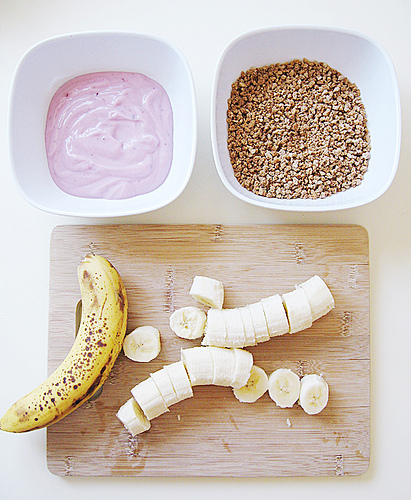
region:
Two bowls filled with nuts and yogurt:
[12, 31, 408, 222]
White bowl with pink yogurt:
[14, 21, 198, 222]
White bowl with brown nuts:
[216, 37, 392, 207]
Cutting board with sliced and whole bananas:
[12, 223, 394, 486]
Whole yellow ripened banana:
[0, 251, 126, 437]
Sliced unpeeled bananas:
[140, 280, 339, 417]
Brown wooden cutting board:
[43, 223, 374, 475]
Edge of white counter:
[323, 480, 408, 497]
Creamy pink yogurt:
[49, 83, 164, 190]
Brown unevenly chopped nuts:
[232, 64, 369, 199]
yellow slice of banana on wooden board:
[294, 274, 339, 332]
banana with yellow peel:
[45, 268, 114, 413]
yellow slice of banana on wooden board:
[290, 373, 339, 427]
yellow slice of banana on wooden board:
[145, 368, 195, 422]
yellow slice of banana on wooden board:
[99, 402, 160, 440]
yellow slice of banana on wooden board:
[182, 265, 231, 313]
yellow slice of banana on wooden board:
[204, 349, 247, 393]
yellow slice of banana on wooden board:
[125, 324, 167, 370]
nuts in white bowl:
[259, 64, 375, 173]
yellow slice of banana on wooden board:
[226, 293, 280, 336]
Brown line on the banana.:
[66, 359, 114, 407]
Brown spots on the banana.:
[62, 343, 105, 381]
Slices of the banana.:
[205, 297, 266, 357]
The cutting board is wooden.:
[238, 436, 314, 472]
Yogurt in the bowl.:
[69, 114, 154, 156]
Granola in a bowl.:
[254, 142, 347, 178]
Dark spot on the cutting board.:
[195, 216, 240, 246]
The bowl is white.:
[41, 47, 180, 79]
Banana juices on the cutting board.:
[98, 424, 149, 473]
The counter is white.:
[379, 320, 410, 379]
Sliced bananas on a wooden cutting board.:
[23, 218, 374, 470]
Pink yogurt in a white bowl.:
[6, 31, 196, 211]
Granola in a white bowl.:
[208, 22, 401, 209]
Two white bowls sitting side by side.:
[6, 25, 401, 214]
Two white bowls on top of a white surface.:
[4, 9, 398, 220]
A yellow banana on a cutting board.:
[0, 252, 127, 433]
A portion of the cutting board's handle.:
[67, 290, 84, 346]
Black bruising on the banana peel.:
[0, 250, 121, 430]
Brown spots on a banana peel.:
[0, 248, 124, 426]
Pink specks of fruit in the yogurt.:
[50, 72, 160, 187]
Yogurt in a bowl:
[40, 78, 169, 186]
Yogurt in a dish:
[38, 90, 174, 199]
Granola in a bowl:
[227, 57, 384, 190]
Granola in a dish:
[217, 60, 362, 199]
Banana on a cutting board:
[7, 237, 127, 447]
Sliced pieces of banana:
[130, 268, 335, 427]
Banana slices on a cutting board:
[127, 281, 330, 418]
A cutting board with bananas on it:
[31, 221, 388, 498]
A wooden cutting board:
[31, 213, 379, 483]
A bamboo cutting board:
[34, 214, 389, 483]